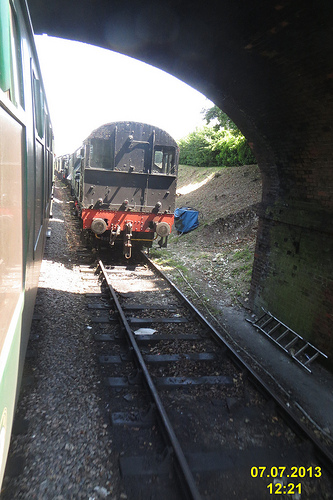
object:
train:
[54, 121, 182, 263]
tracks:
[98, 251, 333, 499]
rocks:
[43, 258, 72, 488]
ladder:
[245, 296, 329, 374]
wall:
[273, 123, 327, 279]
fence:
[0, 8, 54, 292]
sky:
[64, 71, 117, 112]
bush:
[191, 104, 239, 160]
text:
[250, 465, 323, 495]